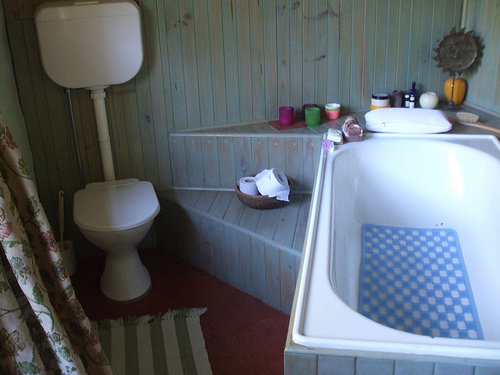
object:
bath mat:
[358, 223, 485, 341]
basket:
[234, 173, 293, 209]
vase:
[443, 77, 466, 106]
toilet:
[36, 1, 162, 304]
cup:
[305, 107, 321, 126]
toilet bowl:
[73, 178, 162, 304]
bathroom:
[1, 0, 500, 375]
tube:
[291, 134, 499, 360]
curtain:
[0, 118, 115, 375]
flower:
[39, 229, 58, 253]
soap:
[327, 128, 343, 143]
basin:
[35, 0, 144, 89]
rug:
[90, 307, 212, 375]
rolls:
[237, 167, 291, 202]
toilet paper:
[237, 167, 291, 202]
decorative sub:
[430, 25, 484, 108]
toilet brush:
[58, 190, 64, 251]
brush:
[431, 26, 481, 109]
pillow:
[364, 107, 454, 133]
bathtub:
[291, 132, 500, 361]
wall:
[71, 0, 462, 189]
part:
[14, 278, 64, 346]